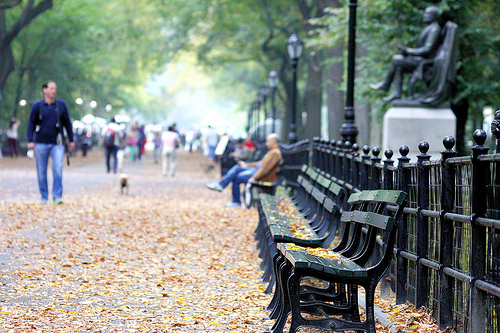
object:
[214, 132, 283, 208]
person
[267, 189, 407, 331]
bench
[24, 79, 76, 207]
man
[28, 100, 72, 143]
sweater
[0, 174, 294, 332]
ground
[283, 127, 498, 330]
fence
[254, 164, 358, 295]
bench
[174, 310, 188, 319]
leaves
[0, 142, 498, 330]
sidewalk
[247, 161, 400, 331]
row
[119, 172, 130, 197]
dog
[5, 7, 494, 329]
photo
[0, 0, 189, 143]
trees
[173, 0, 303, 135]
trees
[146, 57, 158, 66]
leaves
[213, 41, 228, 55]
leaves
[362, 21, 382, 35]
leaves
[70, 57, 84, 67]
leaves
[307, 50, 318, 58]
leaves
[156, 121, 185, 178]
people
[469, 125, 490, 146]
balls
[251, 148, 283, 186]
top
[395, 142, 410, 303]
fence posts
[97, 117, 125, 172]
people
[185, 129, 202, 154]
people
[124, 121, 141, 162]
people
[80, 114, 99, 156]
people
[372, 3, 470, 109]
statue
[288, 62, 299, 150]
lamp posts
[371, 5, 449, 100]
man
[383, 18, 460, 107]
chair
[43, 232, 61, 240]
leaves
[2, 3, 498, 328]
park